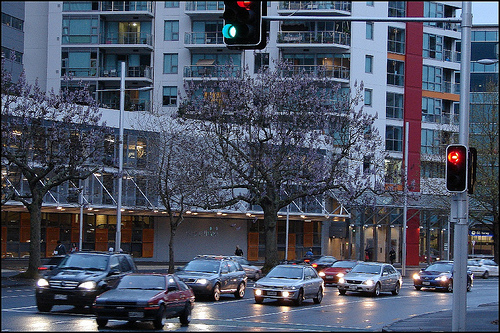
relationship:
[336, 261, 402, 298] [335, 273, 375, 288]
car with headlights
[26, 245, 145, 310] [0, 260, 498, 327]
suv driving on street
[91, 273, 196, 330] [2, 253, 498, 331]
car driving on street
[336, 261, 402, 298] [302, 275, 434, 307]
car driving on street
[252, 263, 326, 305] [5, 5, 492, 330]
car start to move through intersection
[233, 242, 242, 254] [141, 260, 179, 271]
man walks down sidewalk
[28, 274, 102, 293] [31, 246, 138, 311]
headlights on suv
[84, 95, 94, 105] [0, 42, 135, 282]
flower on tree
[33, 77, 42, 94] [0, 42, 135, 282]
flower on tree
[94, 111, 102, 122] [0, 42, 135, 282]
flower on tree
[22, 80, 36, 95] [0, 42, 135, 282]
flower on tree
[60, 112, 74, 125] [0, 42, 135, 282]
flower on tree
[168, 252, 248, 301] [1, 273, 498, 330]
car driving on street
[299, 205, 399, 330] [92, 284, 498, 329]
car driving on street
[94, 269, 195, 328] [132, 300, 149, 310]
car has light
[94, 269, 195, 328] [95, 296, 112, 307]
car has light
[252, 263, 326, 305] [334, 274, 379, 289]
car have lights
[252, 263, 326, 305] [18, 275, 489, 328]
car on street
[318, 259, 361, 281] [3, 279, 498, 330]
car driving on street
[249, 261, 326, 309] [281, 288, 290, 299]
car has lit headlight